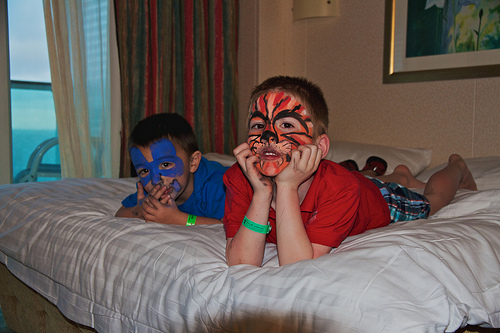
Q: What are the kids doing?
A: Laying down.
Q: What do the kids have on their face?
A: Paint.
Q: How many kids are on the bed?
A: 2.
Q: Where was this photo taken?
A: In a hotel room.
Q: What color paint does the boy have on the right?
A: Orange.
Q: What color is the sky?
A: Blue.